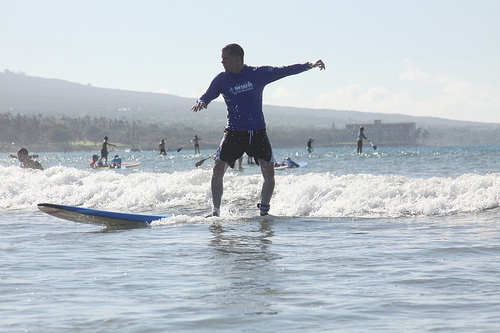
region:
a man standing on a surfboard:
[191, 42, 327, 218]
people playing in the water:
[8, 40, 380, 217]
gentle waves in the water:
[0, 160, 499, 214]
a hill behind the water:
[1, 66, 499, 148]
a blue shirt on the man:
[199, 64, 308, 132]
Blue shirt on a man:
[202, 64, 303, 119]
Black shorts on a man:
[218, 128, 270, 163]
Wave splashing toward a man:
[1, 161, 496, 217]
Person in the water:
[354, 125, 371, 155]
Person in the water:
[9, 147, 46, 172]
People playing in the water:
[89, 136, 139, 173]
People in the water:
[156, 133, 200, 160]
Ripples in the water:
[289, 245, 472, 303]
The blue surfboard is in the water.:
[36, 190, 214, 232]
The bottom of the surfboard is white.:
[42, 205, 146, 240]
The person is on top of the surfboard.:
[193, 35, 338, 219]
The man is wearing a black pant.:
[208, 123, 280, 175]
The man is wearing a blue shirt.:
[196, 60, 298, 132]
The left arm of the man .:
[186, 77, 216, 117]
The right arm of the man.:
[271, 52, 331, 89]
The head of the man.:
[216, 40, 256, 72]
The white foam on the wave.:
[5, 157, 185, 214]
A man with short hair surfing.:
[191, 42, 325, 214]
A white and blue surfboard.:
[36, 202, 166, 229]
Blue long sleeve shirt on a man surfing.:
[202, 62, 315, 131]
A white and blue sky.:
[1, 1, 498, 121]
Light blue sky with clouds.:
[1, 2, 498, 120]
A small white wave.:
[2, 163, 499, 215]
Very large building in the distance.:
[345, 118, 415, 146]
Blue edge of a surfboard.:
[53, 204, 165, 224]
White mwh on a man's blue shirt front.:
[232, 80, 253, 90]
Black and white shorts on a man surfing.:
[214, 128, 276, 168]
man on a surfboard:
[190, 42, 327, 221]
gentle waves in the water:
[0, 164, 499, 214]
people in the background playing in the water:
[5, 125, 378, 169]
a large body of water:
[1, 145, 498, 331]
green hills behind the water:
[0, 70, 499, 147]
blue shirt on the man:
[194, 60, 311, 127]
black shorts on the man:
[215, 124, 274, 166]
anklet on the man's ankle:
[255, 200, 272, 210]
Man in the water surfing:
[192, 42, 326, 214]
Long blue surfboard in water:
[36, 194, 183, 234]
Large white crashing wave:
[0, 166, 499, 221]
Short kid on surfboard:
[99, 132, 114, 165]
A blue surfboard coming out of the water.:
[36, 201, 166, 226]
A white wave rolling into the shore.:
[0, 162, 499, 218]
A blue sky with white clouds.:
[1, 1, 499, 121]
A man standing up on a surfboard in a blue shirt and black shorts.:
[191, 41, 328, 216]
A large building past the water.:
[343, 118, 415, 145]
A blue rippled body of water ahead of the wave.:
[1, 204, 498, 331]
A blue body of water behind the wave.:
[1, 146, 499, 174]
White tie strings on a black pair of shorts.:
[245, 129, 255, 144]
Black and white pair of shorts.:
[212, 126, 275, 169]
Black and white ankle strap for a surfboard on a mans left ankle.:
[255, 202, 270, 212]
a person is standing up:
[192, 45, 332, 216]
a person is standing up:
[302, 130, 321, 157]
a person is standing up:
[188, 132, 208, 159]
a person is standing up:
[155, 135, 170, 156]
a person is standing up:
[98, 132, 112, 162]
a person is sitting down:
[282, 152, 299, 166]